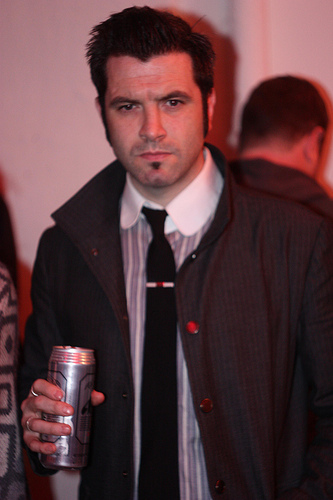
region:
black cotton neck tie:
[138, 206, 180, 499]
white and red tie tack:
[146, 281, 175, 288]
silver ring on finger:
[24, 416, 33, 429]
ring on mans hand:
[31, 383, 37, 397]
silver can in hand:
[44, 345, 91, 470]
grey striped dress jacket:
[25, 143, 331, 498]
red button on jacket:
[198, 398, 212, 414]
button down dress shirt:
[119, 151, 214, 498]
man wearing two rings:
[22, 6, 332, 499]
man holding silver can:
[16, 5, 331, 498]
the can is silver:
[55, 347, 110, 466]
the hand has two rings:
[15, 374, 70, 459]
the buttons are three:
[183, 311, 239, 493]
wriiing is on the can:
[71, 374, 95, 464]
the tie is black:
[146, 210, 179, 280]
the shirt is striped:
[132, 236, 144, 318]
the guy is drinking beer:
[28, 43, 331, 493]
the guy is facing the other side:
[251, 87, 328, 178]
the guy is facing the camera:
[33, 26, 330, 486]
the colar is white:
[162, 176, 226, 216]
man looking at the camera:
[82, 30, 232, 199]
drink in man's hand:
[44, 354, 107, 446]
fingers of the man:
[22, 373, 69, 456]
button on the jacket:
[181, 318, 203, 340]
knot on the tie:
[134, 198, 174, 237]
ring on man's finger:
[26, 379, 42, 402]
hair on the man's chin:
[147, 155, 168, 177]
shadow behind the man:
[218, 30, 245, 74]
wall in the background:
[27, 29, 61, 73]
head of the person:
[230, 66, 324, 176]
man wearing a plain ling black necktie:
[137, 207, 181, 499]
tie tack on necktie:
[145, 282, 171, 288]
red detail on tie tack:
[154, 281, 164, 287]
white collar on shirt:
[119, 144, 223, 236]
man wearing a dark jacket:
[17, 141, 332, 499]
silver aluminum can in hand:
[43, 344, 92, 469]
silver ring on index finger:
[29, 384, 39, 396]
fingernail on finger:
[54, 390, 63, 398]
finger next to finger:
[27, 396, 73, 416]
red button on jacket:
[185, 319, 198, 334]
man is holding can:
[23, 345, 112, 483]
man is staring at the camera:
[110, 84, 198, 129]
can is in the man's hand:
[45, 339, 100, 466]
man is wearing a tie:
[135, 206, 187, 497]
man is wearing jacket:
[22, 145, 332, 480]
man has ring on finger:
[23, 413, 37, 429]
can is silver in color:
[44, 343, 92, 467]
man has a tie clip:
[145, 278, 175, 289]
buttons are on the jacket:
[186, 318, 218, 420]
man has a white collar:
[110, 149, 224, 234]